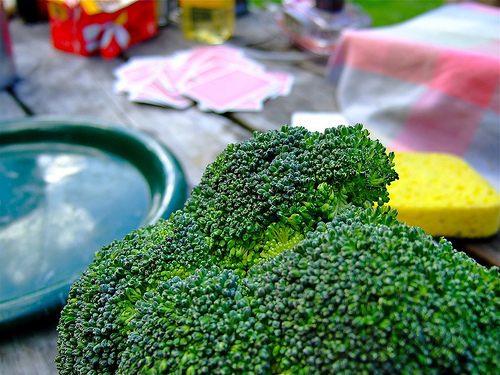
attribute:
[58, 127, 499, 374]
broccoli — raw, green, focused, topped, speared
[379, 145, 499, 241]
sponge — yellow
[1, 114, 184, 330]
plate — green, sunlit, reflected, round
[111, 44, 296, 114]
cards — sprawled, red, piled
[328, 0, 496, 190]
cloth — checkered, red, white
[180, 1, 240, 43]
liquid — yellow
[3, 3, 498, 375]
table — itemed, wooden, large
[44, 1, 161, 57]
box — red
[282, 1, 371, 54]
bottle — black